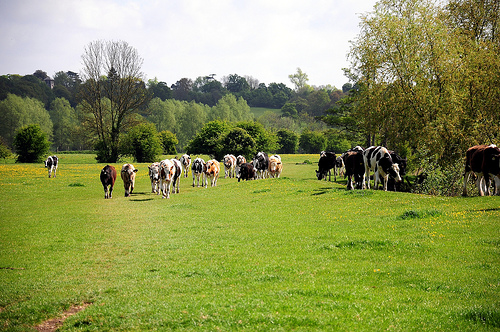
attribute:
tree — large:
[341, 0, 498, 198]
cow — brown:
[86, 153, 124, 202]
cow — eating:
[458, 141, 499, 197]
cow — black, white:
[41, 152, 63, 179]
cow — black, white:
[94, 147, 283, 202]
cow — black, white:
[460, 140, 498, 198]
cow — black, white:
[311, 143, 408, 192]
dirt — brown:
[23, 293, 125, 330]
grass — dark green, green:
[0, 152, 499, 329]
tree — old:
[19, 59, 156, 172]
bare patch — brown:
[28, 295, 93, 330]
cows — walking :
[96, 137, 298, 214]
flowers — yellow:
[3, 166, 32, 173]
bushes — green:
[1, 101, 353, 151]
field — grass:
[8, 156, 498, 327]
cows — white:
[144, 153, 186, 200]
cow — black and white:
[362, 145, 404, 196]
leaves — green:
[374, 17, 484, 145]